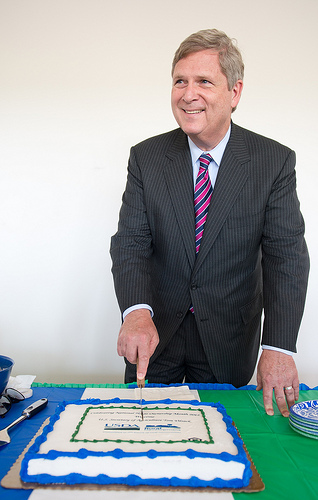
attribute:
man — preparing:
[110, 28, 309, 416]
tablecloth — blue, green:
[224, 373, 262, 422]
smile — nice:
[178, 104, 208, 117]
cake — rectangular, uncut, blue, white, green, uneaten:
[16, 392, 257, 492]